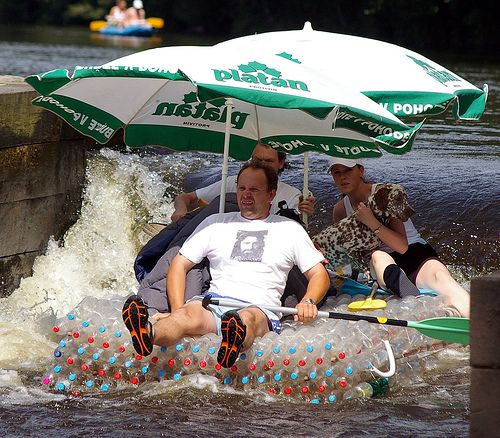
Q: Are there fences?
A: No, there are no fences.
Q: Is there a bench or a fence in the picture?
A: No, there are no fences or benches.